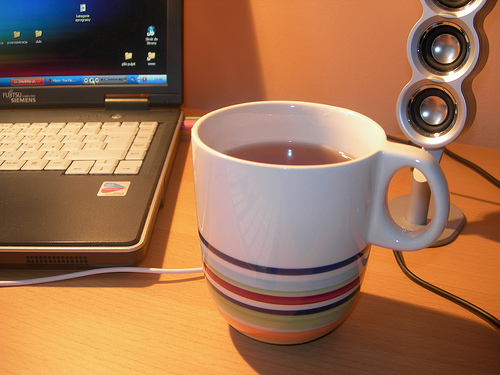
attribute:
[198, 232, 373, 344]
stripes — multicolored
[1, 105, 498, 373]
table — pale wood, wooden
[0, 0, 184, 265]
laptop — open, on, powered on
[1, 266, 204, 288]
cord — white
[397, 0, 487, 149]
speaker — silver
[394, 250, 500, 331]
cord — dark gray, black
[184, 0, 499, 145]
wall — peach colored, tan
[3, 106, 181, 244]
keyboard — gray, white